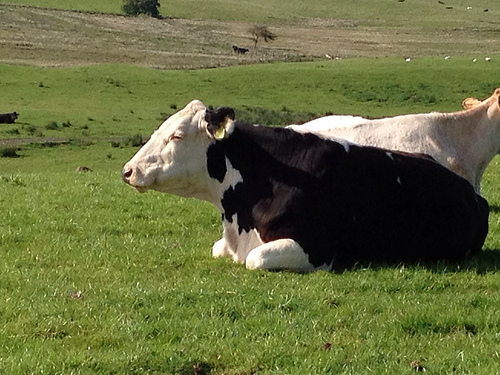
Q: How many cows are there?
A: Two.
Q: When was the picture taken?
A: Daytime.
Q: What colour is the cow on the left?
A: White.